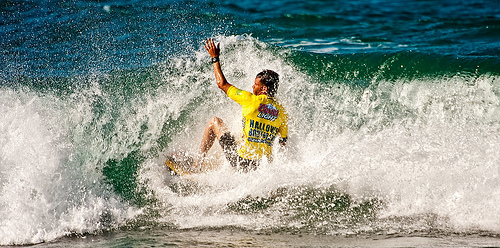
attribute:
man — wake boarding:
[158, 35, 300, 189]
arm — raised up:
[202, 33, 244, 107]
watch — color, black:
[315, 73, 442, 176]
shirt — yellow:
[225, 84, 295, 174]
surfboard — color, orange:
[135, 131, 299, 221]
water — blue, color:
[375, 11, 447, 41]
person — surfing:
[184, 32, 289, 186]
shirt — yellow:
[207, 75, 308, 166]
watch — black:
[211, 56, 221, 64]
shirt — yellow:
[205, 83, 323, 167]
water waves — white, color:
[1, 35, 499, 241]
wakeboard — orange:
[133, 151, 255, 211]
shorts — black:
[211, 124, 278, 179]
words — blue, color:
[244, 115, 282, 144]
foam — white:
[370, 72, 481, 192]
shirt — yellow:
[225, 85, 289, 159]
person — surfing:
[154, 31, 324, 210]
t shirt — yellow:
[222, 83, 289, 165]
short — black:
[214, 132, 259, 175]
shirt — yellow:
[230, 84, 298, 164]